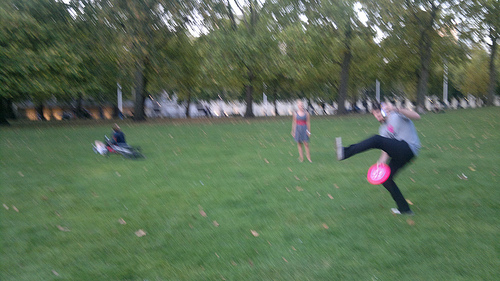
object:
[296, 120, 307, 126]
belt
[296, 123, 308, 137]
woman's waist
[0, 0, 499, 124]
trees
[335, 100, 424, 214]
man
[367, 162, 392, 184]
frisbee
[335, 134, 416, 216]
legs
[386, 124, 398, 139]
design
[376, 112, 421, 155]
shirt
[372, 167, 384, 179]
design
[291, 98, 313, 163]
person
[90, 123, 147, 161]
person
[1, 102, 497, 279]
field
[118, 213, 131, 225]
leaf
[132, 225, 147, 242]
leaf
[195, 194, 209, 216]
leaf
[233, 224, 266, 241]
leaf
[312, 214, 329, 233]
leaf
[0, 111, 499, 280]
grass